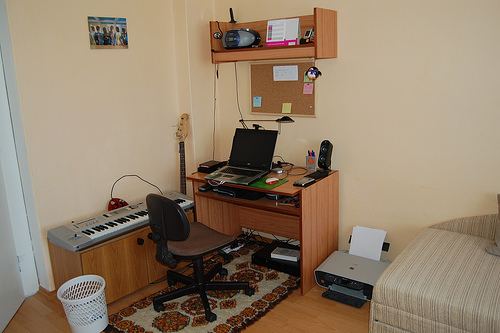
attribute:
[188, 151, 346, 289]
desk — wooden, brown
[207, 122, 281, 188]
laptop — black, open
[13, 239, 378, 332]
floor — wood, brown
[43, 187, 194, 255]
keyboard — silver, musical, electronic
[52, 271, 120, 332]
trash can — white, small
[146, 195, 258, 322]
office chair — small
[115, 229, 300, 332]
rug — flowered, black, white, orange, colorful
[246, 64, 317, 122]
corkboard — small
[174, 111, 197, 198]
guitar — electric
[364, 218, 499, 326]
couch — striped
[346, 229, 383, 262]
paper — white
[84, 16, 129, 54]
poster — small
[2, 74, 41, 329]
door — open